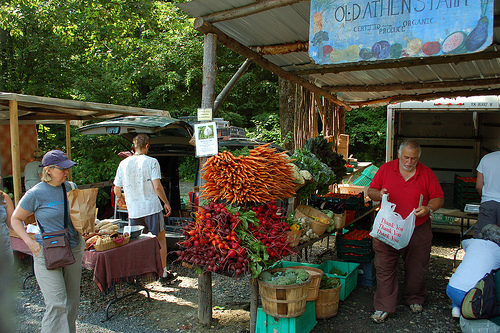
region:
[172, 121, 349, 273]
piles of vegetables on display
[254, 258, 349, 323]
baskets full of vegetables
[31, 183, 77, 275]
a brown bag slung over a woman's shoulder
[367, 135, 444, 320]
a man carrying a plastic bag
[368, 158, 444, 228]
a man wearing a red shirt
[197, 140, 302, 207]
a huge pile of carrots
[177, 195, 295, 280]
a huge pile of radishes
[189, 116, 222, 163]
a white sign posted on a wooden post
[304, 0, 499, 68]
a worn hand drawn sign for the vegetable stand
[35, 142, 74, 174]
woman wearing a blue hat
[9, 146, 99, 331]
woman carrying a brown paper bag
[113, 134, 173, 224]
back of man wearing a white t shirt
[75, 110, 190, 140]
the raised rear hatch of a mini van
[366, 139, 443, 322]
man in red shirt holding a plastic bag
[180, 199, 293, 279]
several varieties of radishes in a pile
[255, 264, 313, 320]
bushel basket full of green produce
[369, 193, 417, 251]
white plastic bag with thank you written on it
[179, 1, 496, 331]
an organic produce stand at a farmers market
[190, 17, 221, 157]
white sign attached to a wooden pole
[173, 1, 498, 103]
corrugated metal roof with a blue sign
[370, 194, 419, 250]
a white plastic bag in a man's hands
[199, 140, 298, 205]
a bunch of carrots on a shelf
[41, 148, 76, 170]
woman wearing a blue cap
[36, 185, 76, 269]
a woman carrying a brown purse on her shoulder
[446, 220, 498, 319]
a person crouching down on the floor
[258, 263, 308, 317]
a basket full of green vegetable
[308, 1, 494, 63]
a blue sign over a stall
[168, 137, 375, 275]
a bunch of different veggies in a stall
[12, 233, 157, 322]
a table with a red tablecloth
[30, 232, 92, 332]
Woman wearing pants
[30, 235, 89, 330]
Woman is wearing pants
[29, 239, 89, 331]
Woman wearing gray pants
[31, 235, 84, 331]
Woman is wearing gray pants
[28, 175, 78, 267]
Woman carrying a purse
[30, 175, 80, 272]
Woman is carrying a purse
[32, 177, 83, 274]
Woman carrying a brown purse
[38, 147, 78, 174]
Woman wearing a hat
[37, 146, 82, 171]
Woman is wearing a hat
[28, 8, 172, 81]
The tree leaves are green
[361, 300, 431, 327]
The shoes on the man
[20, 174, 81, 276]
The woman is wearing a bag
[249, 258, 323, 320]
The basket of fruit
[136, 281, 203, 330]
The ground is made of dirt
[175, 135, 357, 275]
A variety of different vegetables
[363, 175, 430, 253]
The man carrying the bag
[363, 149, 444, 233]
The man is wearing a red shirt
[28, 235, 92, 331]
The woman has on khaki pants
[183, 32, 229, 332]
The pole is made of wood